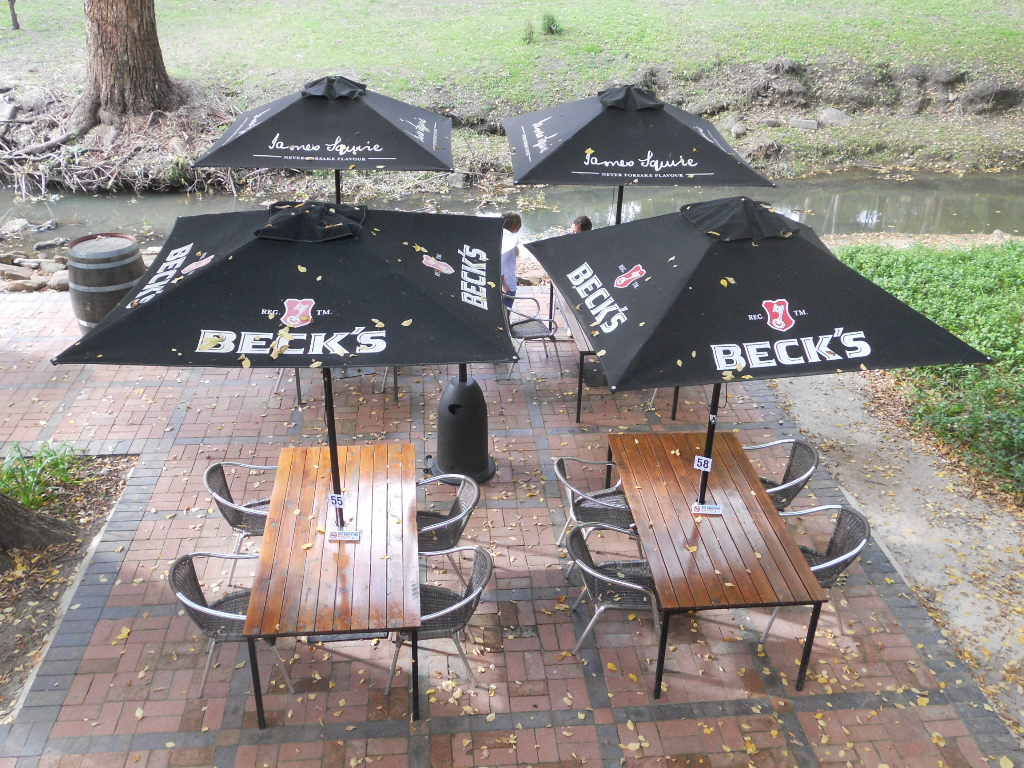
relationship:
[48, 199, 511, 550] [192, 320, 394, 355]
umbrella with letters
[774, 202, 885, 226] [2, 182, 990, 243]
light reflecting in water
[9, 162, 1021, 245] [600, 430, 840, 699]
creek beside table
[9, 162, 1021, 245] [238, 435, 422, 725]
creek beside table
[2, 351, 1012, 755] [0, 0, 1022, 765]
bricks on ground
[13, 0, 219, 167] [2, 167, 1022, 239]
tree trunk beside creek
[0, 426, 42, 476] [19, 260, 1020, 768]
leaves covering ground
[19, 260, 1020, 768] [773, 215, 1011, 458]
ground with grass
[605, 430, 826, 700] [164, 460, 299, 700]
table with chairs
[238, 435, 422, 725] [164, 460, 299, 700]
table with chairs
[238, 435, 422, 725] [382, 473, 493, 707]
table with chairs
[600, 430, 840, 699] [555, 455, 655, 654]
table with chairs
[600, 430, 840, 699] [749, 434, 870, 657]
table with chairs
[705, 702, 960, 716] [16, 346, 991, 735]
leaves scattered ground